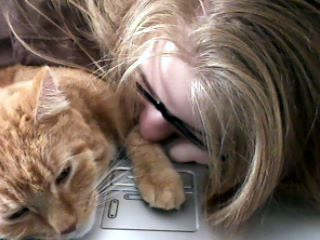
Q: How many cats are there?
A: One.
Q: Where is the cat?
A: On the laptop.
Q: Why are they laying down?
A: They are tired.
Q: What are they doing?
A: Sleeping.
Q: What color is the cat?
A: Orange.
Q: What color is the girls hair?
A: Blonde.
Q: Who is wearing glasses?
A: The girl.